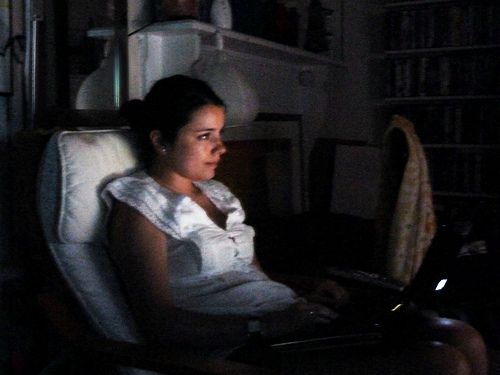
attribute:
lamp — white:
[201, 32, 260, 132]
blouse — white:
[100, 174, 299, 308]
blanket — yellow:
[348, 116, 479, 258]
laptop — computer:
[259, 260, 479, 355]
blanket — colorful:
[383, 107, 438, 294]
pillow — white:
[45, 132, 131, 339]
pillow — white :
[43, 120, 144, 335]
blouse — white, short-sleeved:
[102, 166, 318, 333]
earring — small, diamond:
[156, 141, 166, 148]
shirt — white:
[95, 163, 303, 316]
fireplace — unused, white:
[220, 126, 307, 247]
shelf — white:
[182, 29, 320, 83]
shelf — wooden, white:
[142, 4, 329, 71]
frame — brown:
[252, 110, 304, 219]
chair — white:
[50, 125, 196, 372]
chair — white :
[49, 115, 132, 358]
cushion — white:
[44, 127, 173, 348]